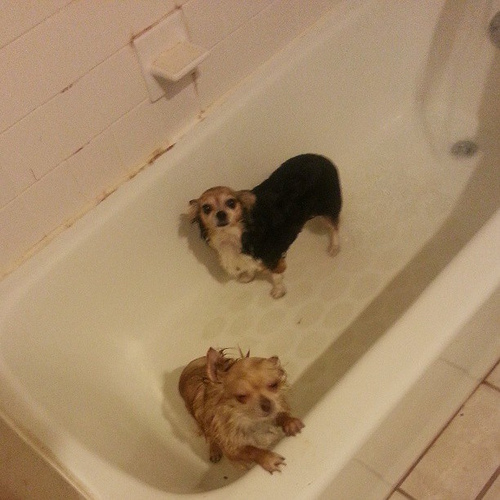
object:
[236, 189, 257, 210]
ear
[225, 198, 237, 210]
eyes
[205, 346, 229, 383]
dog ear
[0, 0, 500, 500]
bathtub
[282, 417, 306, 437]
paw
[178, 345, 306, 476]
dog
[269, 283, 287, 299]
paw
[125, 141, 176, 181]
grout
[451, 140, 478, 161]
drain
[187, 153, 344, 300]
dog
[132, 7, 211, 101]
holder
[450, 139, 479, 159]
silver drain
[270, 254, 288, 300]
legs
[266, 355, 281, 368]
ear